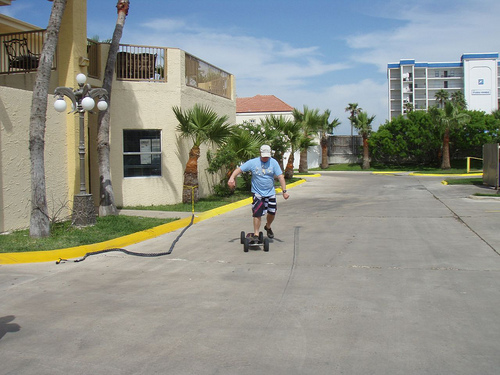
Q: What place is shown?
A: It is a road.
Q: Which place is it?
A: It is a road.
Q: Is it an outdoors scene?
A: Yes, it is outdoors.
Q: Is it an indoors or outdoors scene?
A: It is outdoors.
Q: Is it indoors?
A: No, it is outdoors.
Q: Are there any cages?
A: No, there are no cages.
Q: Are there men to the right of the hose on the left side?
A: Yes, there is a man to the right of the hose.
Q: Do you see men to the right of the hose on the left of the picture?
A: Yes, there is a man to the right of the hose.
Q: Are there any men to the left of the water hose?
A: No, the man is to the right of the water hose.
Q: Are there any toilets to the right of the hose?
A: No, there is a man to the right of the hose.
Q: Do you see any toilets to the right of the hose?
A: No, there is a man to the right of the hose.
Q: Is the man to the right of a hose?
A: Yes, the man is to the right of a hose.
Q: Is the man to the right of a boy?
A: No, the man is to the right of a hose.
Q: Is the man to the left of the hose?
A: No, the man is to the right of the hose.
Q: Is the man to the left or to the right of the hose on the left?
A: The man is to the right of the water hose.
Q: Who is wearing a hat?
A: The man is wearing a hat.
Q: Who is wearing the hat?
A: The man is wearing a hat.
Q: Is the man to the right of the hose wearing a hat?
A: Yes, the man is wearing a hat.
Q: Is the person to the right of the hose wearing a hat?
A: Yes, the man is wearing a hat.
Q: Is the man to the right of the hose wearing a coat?
A: No, the man is wearing a hat.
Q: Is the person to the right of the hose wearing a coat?
A: No, the man is wearing a hat.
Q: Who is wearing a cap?
A: The man is wearing a cap.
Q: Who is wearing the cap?
A: The man is wearing a cap.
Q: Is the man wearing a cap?
A: Yes, the man is wearing a cap.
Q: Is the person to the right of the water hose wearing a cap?
A: Yes, the man is wearing a cap.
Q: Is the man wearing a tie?
A: No, the man is wearing a cap.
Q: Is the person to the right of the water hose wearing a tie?
A: No, the man is wearing a cap.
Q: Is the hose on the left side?
A: Yes, the hose is on the left of the image.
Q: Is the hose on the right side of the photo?
A: No, the hose is on the left of the image.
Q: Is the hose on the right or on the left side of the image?
A: The hose is on the left of the image.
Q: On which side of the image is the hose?
A: The hose is on the left of the image.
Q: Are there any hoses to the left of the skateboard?
A: Yes, there is a hose to the left of the skateboard.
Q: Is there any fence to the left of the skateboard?
A: No, there is a hose to the left of the skateboard.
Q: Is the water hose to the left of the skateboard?
A: Yes, the water hose is to the left of the skateboard.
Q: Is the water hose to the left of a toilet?
A: No, the water hose is to the left of the skateboard.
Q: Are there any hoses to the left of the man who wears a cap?
A: Yes, there is a hose to the left of the man.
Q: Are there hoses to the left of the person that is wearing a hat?
A: Yes, there is a hose to the left of the man.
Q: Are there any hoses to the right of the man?
A: No, the hose is to the left of the man.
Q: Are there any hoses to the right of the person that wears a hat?
A: No, the hose is to the left of the man.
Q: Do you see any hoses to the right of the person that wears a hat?
A: No, the hose is to the left of the man.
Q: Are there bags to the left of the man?
A: No, there is a hose to the left of the man.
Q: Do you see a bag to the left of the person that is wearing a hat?
A: No, there is a hose to the left of the man.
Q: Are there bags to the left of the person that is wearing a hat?
A: No, there is a hose to the left of the man.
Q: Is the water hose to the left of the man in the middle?
A: Yes, the water hose is to the left of the man.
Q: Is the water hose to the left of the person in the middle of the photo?
A: Yes, the water hose is to the left of the man.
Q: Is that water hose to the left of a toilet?
A: No, the water hose is to the left of the man.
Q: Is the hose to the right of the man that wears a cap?
A: No, the hose is to the left of the man.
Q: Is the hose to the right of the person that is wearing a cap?
A: No, the hose is to the left of the man.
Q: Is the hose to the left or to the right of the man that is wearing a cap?
A: The hose is to the left of the man.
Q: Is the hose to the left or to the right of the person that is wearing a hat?
A: The hose is to the left of the man.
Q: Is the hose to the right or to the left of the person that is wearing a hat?
A: The hose is to the left of the man.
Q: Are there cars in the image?
A: No, there are no cars.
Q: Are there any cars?
A: No, there are no cars.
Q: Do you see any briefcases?
A: No, there are no briefcases.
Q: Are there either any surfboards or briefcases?
A: No, there are no briefcases or surfboards.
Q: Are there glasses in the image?
A: No, there are no glasses.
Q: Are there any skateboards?
A: Yes, there is a skateboard.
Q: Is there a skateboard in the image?
A: Yes, there is a skateboard.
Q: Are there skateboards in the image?
A: Yes, there is a skateboard.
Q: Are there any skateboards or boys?
A: Yes, there is a skateboard.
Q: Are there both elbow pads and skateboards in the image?
A: No, there is a skateboard but no elbow pads.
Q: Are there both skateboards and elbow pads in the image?
A: No, there is a skateboard but no elbow pads.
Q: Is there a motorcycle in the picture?
A: No, there are no motorcycles.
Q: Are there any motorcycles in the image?
A: No, there are no motorcycles.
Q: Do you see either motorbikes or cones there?
A: No, there are no motorbikes or cones.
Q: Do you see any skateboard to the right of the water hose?
A: Yes, there is a skateboard to the right of the water hose.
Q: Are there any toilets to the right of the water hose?
A: No, there is a skateboard to the right of the water hose.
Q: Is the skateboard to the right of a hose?
A: Yes, the skateboard is to the right of a hose.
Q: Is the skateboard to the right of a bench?
A: No, the skateboard is to the right of a hose.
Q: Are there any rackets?
A: No, there are no rackets.